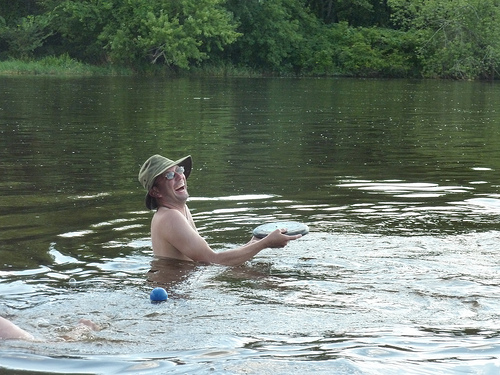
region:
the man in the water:
[126, 150, 289, 267]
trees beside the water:
[17, 8, 499, 64]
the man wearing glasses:
[148, 157, 191, 194]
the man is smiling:
[137, 148, 277, 286]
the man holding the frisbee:
[123, 153, 340, 288]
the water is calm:
[22, 70, 498, 210]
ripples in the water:
[215, 225, 498, 367]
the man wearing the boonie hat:
[114, 143, 211, 217]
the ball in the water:
[141, 280, 170, 308]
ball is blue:
[142, 285, 174, 306]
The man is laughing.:
[108, 133, 335, 315]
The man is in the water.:
[106, 135, 338, 297]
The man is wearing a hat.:
[113, 113, 330, 320]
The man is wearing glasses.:
[90, 129, 333, 324]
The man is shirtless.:
[101, 130, 343, 321]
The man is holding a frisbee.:
[114, 135, 344, 323]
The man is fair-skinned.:
[97, 120, 337, 339]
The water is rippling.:
[7, 77, 497, 374]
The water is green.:
[1, 78, 498, 373]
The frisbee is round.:
[236, 200, 326, 257]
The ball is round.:
[128, 269, 205, 338]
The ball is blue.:
[129, 270, 211, 320]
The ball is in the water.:
[123, 271, 196, 321]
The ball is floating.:
[121, 271, 212, 336]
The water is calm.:
[2, 73, 497, 368]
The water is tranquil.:
[1, 70, 498, 373]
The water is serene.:
[3, 72, 495, 374]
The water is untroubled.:
[0, 71, 498, 371]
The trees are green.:
[0, 1, 498, 79]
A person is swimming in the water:
[118, 61, 440, 342]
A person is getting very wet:
[126, 100, 476, 332]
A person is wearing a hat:
[116, 85, 458, 321]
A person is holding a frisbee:
[120, 111, 448, 321]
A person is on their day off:
[123, 117, 473, 343]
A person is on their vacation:
[120, 98, 422, 323]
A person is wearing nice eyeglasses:
[133, 121, 404, 322]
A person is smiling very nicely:
[135, 138, 205, 219]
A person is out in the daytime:
[115, 58, 462, 305]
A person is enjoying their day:
[137, 112, 439, 339]